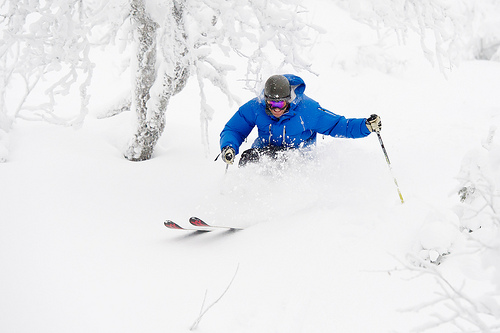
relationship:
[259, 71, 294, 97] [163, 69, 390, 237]
hat of skier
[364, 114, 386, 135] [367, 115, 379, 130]
glove on hand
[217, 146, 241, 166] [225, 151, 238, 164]
glove on hand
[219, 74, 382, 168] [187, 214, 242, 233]
man wearing ski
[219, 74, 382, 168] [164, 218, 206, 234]
man wearing ski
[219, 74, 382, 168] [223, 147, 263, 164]
man wearing glove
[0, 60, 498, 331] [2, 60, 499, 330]
snow on ground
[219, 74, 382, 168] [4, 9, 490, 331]
man surrounded by snow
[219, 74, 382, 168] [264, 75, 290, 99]
man wearing hat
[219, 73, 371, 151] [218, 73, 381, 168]
coat on man